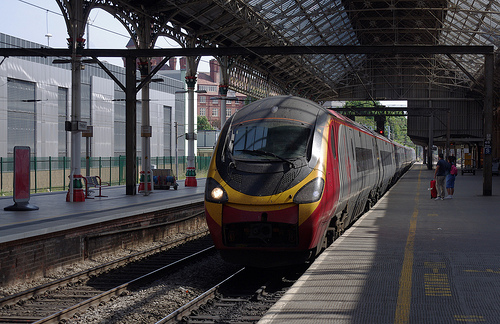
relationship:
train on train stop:
[192, 91, 422, 278] [4, 0, 494, 320]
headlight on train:
[205, 181, 227, 205] [207, 93, 422, 270]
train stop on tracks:
[4, 0, 494, 320] [3, 210, 296, 321]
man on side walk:
[433, 153, 448, 201] [252, 160, 496, 322]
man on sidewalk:
[433, 153, 448, 201] [399, 166, 489, 321]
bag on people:
[429, 181, 436, 200] [431, 150, 458, 195]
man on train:
[433, 153, 448, 201] [203, 92, 414, 284]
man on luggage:
[433, 155, 446, 197] [429, 179, 437, 200]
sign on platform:
[6, 141, 46, 212] [0, 179, 211, 237]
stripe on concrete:
[385, 166, 425, 322] [365, 172, 497, 318]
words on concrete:
[422, 249, 453, 300] [365, 172, 497, 318]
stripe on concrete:
[385, 166, 425, 322] [256, 161, 497, 318]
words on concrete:
[422, 249, 453, 300] [256, 161, 497, 318]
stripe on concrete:
[390, 162, 422, 322] [256, 161, 497, 318]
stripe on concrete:
[385, 166, 425, 322] [247, 148, 499, 320]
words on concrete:
[411, 248, 458, 305] [247, 148, 499, 320]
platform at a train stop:
[1, 165, 202, 314] [4, 0, 494, 320]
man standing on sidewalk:
[433, 153, 448, 201] [268, 144, 497, 320]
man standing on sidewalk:
[433, 153, 448, 201] [264, 162, 498, 322]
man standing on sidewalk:
[433, 153, 448, 201] [233, 153, 498, 320]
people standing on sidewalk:
[433, 152, 465, 192] [268, 144, 497, 320]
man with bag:
[433, 153, 448, 201] [424, 175, 445, 204]